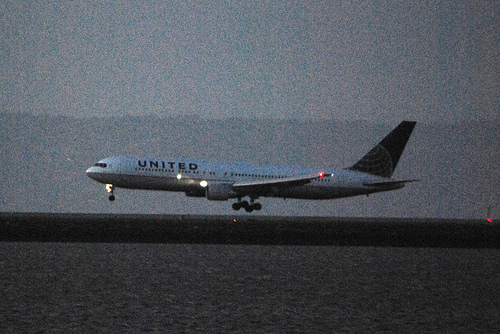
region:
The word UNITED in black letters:
[137, 156, 198, 171]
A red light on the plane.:
[317, 172, 325, 178]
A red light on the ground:
[486, 214, 493, 222]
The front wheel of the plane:
[104, 181, 116, 203]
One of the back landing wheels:
[246, 194, 260, 212]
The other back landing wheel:
[230, 196, 247, 211]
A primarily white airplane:
[86, 118, 420, 215]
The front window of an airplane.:
[92, 160, 107, 168]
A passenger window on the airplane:
[209, 170, 214, 176]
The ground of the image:
[0, 211, 499, 332]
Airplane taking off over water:
[70, 117, 418, 212]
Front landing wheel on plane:
[105, 190, 115, 195]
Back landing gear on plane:
[227, 200, 257, 210]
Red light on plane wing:
[315, 170, 320, 176]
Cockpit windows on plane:
[90, 157, 105, 167]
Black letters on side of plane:
[136, 156, 196, 166]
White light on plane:
[175, 170, 182, 180]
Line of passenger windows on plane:
[130, 165, 276, 175]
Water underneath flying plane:
[0, 240, 498, 332]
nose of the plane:
[85, 165, 92, 175]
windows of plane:
[134, 165, 160, 172]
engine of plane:
[206, 186, 242, 198]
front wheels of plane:
[106, 192, 116, 199]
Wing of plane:
[233, 176, 341, 189]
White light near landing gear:
[105, 180, 113, 189]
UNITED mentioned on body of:
[136, 158, 198, 170]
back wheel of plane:
[232, 198, 261, 211]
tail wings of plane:
[351, 117, 416, 172]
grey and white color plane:
[86, 155, 351, 196]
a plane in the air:
[56, 107, 433, 241]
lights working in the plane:
[166, 161, 218, 197]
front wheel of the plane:
[98, 190, 120, 205]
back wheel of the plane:
[224, 195, 276, 215]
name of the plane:
[128, 131, 203, 182]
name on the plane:
[131, 140, 218, 192]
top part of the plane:
[349, 120, 427, 173]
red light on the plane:
[309, 169, 330, 190]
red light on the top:
[481, 213, 498, 228]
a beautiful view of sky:
[16, 21, 499, 145]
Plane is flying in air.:
[75, 115, 436, 222]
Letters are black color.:
[128, 153, 203, 177]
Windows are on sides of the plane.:
[130, 161, 336, 186]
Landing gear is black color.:
[102, 185, 262, 217]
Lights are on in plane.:
[90, 156, 336, 216]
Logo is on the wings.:
[350, 117, 420, 189]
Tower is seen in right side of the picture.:
[465, 190, 492, 230]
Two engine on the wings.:
[173, 180, 244, 208]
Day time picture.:
[27, 13, 484, 318]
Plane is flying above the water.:
[88, 133, 412, 279]